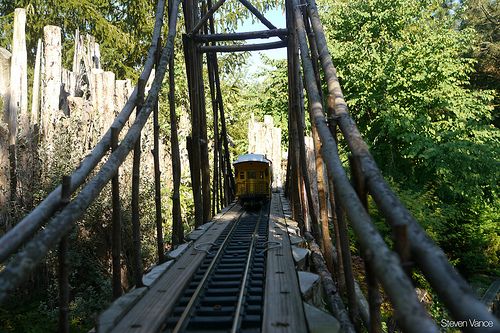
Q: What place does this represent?
A: It represents the forest.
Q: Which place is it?
A: It is a forest.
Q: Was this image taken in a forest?
A: Yes, it was taken in a forest.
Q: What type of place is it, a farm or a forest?
A: It is a forest.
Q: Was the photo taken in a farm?
A: No, the picture was taken in a forest.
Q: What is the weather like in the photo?
A: It is clear.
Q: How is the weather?
A: It is clear.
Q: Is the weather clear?
A: Yes, it is clear.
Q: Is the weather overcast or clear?
A: It is clear.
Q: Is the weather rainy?
A: No, it is clear.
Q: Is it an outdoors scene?
A: Yes, it is outdoors.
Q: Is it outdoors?
A: Yes, it is outdoors.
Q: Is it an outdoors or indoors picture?
A: It is outdoors.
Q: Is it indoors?
A: No, it is outdoors.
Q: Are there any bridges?
A: Yes, there is a bridge.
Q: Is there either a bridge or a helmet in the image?
A: Yes, there is a bridge.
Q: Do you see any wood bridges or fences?
A: Yes, there is a wood bridge.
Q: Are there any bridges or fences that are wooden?
A: Yes, the bridge is wooden.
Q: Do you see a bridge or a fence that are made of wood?
A: Yes, the bridge is made of wood.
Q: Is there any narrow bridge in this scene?
A: Yes, there is a narrow bridge.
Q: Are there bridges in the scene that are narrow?
A: Yes, there is a bridge that is narrow.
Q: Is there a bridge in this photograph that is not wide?
A: Yes, there is a narrow bridge.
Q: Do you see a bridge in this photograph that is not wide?
A: Yes, there is a narrow bridge.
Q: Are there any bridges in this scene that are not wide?
A: Yes, there is a narrow bridge.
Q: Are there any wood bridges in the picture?
A: Yes, there is a wood bridge.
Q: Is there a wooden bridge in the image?
A: Yes, there is a wood bridge.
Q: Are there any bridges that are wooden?
A: Yes, there is a bridge that is wooden.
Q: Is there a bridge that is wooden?
A: Yes, there is a bridge that is wooden.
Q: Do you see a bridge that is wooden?
A: Yes, there is a bridge that is wooden.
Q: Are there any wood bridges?
A: Yes, there is a bridge that is made of wood.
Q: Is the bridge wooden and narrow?
A: Yes, the bridge is wooden and narrow.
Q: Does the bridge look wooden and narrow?
A: Yes, the bridge is wooden and narrow.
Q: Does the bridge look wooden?
A: Yes, the bridge is wooden.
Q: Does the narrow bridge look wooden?
A: Yes, the bridge is wooden.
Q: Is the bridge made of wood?
A: Yes, the bridge is made of wood.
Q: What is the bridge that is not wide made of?
A: The bridge is made of wood.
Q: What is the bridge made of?
A: The bridge is made of wood.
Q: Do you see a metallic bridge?
A: No, there is a bridge but it is wooden.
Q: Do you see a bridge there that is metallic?
A: No, there is a bridge but it is wooden.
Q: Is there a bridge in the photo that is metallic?
A: No, there is a bridge but it is wooden.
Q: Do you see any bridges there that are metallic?
A: No, there is a bridge but it is wooden.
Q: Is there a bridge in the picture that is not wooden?
A: No, there is a bridge but it is wooden.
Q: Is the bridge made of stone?
A: No, the bridge is made of wood.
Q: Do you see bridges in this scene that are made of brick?
A: No, there is a bridge but it is made of wood.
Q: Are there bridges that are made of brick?
A: No, there is a bridge but it is made of wood.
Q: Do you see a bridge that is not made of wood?
A: No, there is a bridge but it is made of wood.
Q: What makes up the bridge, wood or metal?
A: The bridge is made of wood.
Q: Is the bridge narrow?
A: Yes, the bridge is narrow.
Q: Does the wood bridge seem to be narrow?
A: Yes, the bridge is narrow.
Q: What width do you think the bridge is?
A: The bridge is narrow.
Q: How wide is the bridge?
A: The bridge is narrow.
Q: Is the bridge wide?
A: No, the bridge is narrow.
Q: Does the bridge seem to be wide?
A: No, the bridge is narrow.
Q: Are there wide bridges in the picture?
A: No, there is a bridge but it is narrow.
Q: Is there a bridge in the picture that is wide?
A: No, there is a bridge but it is narrow.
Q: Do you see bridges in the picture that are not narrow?
A: No, there is a bridge but it is narrow.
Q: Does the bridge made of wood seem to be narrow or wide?
A: The bridge is narrow.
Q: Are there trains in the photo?
A: Yes, there is a train.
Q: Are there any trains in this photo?
A: Yes, there is a train.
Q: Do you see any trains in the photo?
A: Yes, there is a train.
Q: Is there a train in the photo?
A: Yes, there is a train.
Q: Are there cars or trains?
A: Yes, there is a train.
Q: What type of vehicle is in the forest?
A: The vehicle is a train.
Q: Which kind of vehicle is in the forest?
A: The vehicle is a train.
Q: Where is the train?
A: The train is in the forest.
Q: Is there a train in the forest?
A: Yes, there is a train in the forest.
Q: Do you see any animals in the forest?
A: No, there is a train in the forest.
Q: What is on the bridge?
A: The train is on the bridge.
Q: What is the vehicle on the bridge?
A: The vehicle is a train.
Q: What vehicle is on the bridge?
A: The vehicle is a train.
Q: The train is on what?
A: The train is on the bridge.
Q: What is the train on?
A: The train is on the bridge.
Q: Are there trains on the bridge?
A: Yes, there is a train on the bridge.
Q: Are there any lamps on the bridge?
A: No, there is a train on the bridge.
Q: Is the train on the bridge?
A: Yes, the train is on the bridge.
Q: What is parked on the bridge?
A: The train is parked on the bridge.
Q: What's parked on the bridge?
A: The train is parked on the bridge.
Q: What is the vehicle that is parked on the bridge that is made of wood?
A: The vehicle is a train.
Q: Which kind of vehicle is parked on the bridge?
A: The vehicle is a train.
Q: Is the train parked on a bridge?
A: Yes, the train is parked on a bridge.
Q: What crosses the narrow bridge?
A: The train crosses the bridge.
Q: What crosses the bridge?
A: The train crosses the bridge.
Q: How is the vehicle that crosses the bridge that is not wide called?
A: The vehicle is a train.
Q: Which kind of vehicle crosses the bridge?
A: The vehicle is a train.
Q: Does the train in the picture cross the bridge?
A: Yes, the train crosses the bridge.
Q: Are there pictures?
A: No, there are no pictures.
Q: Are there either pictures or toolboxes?
A: No, there are no pictures or toolboxes.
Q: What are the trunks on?
A: The trunks are on the trees.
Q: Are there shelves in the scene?
A: No, there are no shelves.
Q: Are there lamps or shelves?
A: No, there are no shelves or lamps.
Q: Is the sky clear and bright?
A: Yes, the sky is clear and bright.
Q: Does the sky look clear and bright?
A: Yes, the sky is clear and bright.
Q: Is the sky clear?
A: Yes, the sky is clear.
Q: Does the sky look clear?
A: Yes, the sky is clear.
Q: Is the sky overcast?
A: No, the sky is clear.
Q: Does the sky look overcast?
A: No, the sky is clear.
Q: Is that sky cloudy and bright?
A: No, the sky is bright but clear.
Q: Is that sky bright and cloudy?
A: No, the sky is bright but clear.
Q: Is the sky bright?
A: Yes, the sky is bright.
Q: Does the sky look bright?
A: Yes, the sky is bright.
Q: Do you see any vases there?
A: No, there are no vases.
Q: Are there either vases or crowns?
A: No, there are no vases or crowns.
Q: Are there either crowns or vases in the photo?
A: No, there are no vases or crowns.